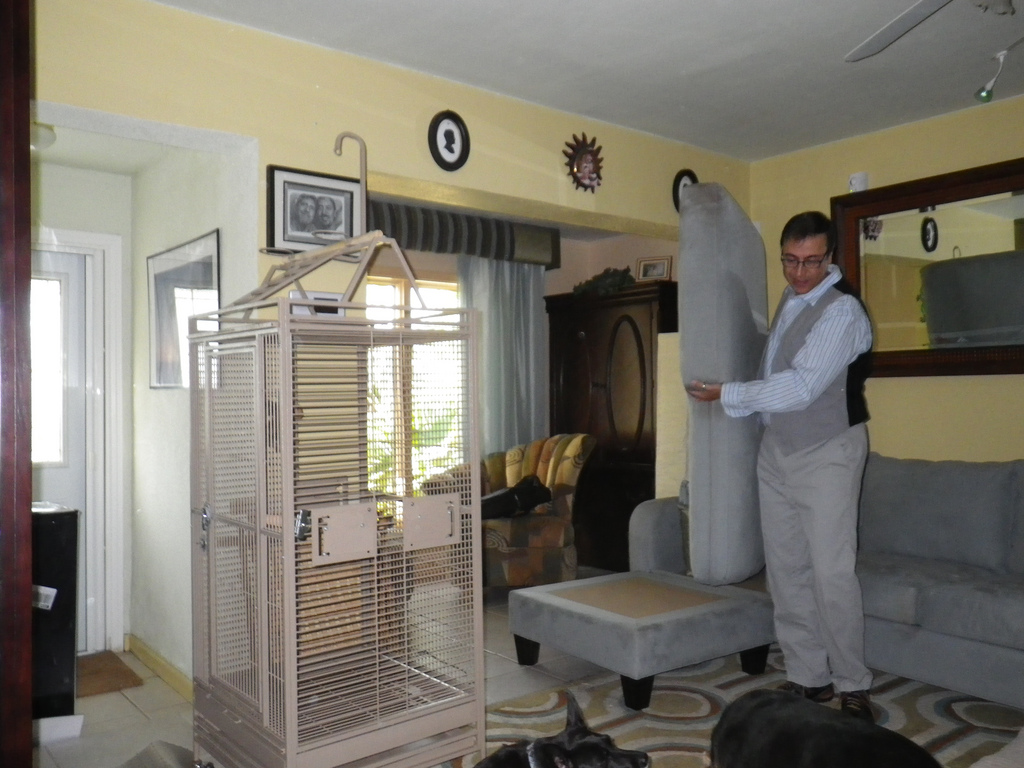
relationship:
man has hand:
[683, 207, 878, 713] [686, 374, 725, 403]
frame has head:
[427, 110, 470, 171] [441, 129, 455, 142]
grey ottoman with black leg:
[510, 574, 774, 708] [733, 648, 768, 674]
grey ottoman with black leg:
[510, 574, 774, 708] [621, 680, 652, 707]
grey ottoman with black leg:
[510, 574, 774, 708] [512, 641, 538, 672]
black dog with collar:
[482, 697, 658, 764] [523, 734, 549, 763]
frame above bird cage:
[266, 164, 368, 263] [187, 232, 489, 768]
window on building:
[29, 276, 68, 462] [39, 8, 992, 763]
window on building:
[365, 275, 463, 533] [39, 8, 992, 763]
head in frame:
[444, 129, 457, 154] [430, 112, 467, 171]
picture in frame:
[286, 183, 349, 244] [256, 164, 373, 257]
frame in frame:
[145, 229, 224, 390] [145, 230, 230, 397]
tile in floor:
[124, 675, 191, 721] [83, 645, 190, 764]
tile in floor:
[158, 693, 197, 730] [74, 656, 185, 760]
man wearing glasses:
[683, 207, 878, 713] [782, 246, 824, 272]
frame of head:
[427, 110, 470, 171] [437, 131, 464, 157]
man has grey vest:
[683, 207, 878, 713] [755, 284, 874, 464]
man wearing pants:
[683, 207, 878, 713] [750, 417, 874, 694]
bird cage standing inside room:
[182, 225, 492, 764] [3, 3, 993, 764]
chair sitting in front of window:
[418, 428, 598, 603] [364, 273, 466, 522]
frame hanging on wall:
[145, 229, 224, 390] [134, 134, 256, 698]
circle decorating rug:
[616, 673, 725, 726] [366, 642, 993, 764]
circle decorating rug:
[765, 644, 792, 673] [366, 642, 993, 764]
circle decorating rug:
[485, 687, 572, 718] [366, 642, 993, 764]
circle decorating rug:
[619, 731, 717, 764] [366, 642, 993, 764]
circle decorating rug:
[450, 720, 544, 764] [366, 642, 993, 764]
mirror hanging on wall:
[826, 156, 993, 377] [748, 91, 993, 463]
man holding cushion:
[683, 207, 878, 713] [673, 178, 771, 589]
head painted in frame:
[444, 129, 457, 154] [427, 110, 470, 171]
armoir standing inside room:
[539, 279, 676, 569] [363, 188, 696, 660]